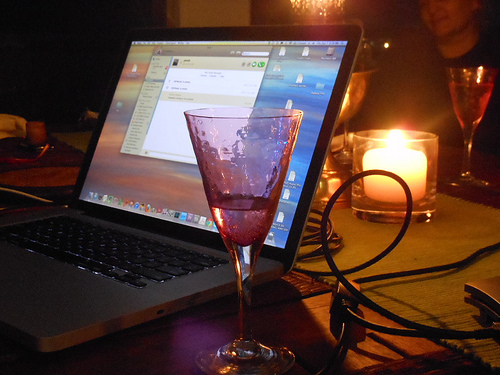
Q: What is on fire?
A: A candle.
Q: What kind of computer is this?
A: Laptop.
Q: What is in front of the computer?
A: A glass.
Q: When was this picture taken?
A: At night.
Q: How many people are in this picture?
A: One.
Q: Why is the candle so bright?
A: It's on fire.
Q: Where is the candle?
A: Behind the computer.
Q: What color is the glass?
A: Pink.